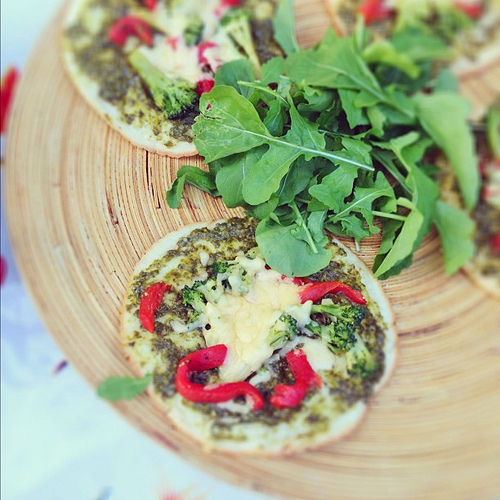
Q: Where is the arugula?
A: Center.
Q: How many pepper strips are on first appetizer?
A: 4.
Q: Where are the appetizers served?
A: On a Plate.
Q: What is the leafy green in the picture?
A: Arugula.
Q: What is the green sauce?
A: Pesto.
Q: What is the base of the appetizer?
A: Cracker.